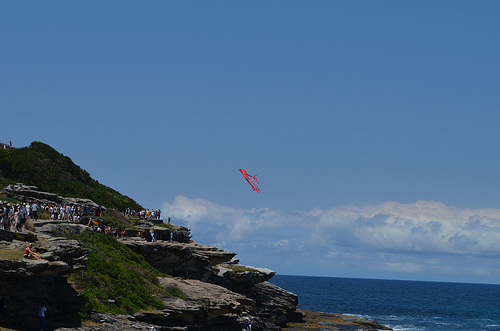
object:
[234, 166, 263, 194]
kite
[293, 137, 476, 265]
air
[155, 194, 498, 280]
clouds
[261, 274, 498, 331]
ocean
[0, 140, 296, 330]
hill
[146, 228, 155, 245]
people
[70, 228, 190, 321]
grass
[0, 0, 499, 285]
sky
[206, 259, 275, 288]
rocks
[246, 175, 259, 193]
tail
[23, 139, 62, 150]
top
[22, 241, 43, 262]
person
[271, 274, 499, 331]
wave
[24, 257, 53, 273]
rock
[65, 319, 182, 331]
rock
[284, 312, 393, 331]
plateau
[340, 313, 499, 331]
foam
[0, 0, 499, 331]
background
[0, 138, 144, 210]
forest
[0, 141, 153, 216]
hill top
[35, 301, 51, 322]
man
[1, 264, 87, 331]
cave